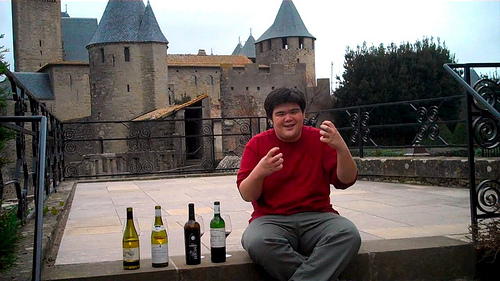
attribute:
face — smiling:
[270, 100, 306, 140]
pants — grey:
[240, 210, 363, 280]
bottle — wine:
[121, 206, 141, 270]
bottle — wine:
[150, 205, 170, 267]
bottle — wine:
[183, 204, 201, 264]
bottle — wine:
[209, 200, 226, 262]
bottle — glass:
[178, 200, 202, 264]